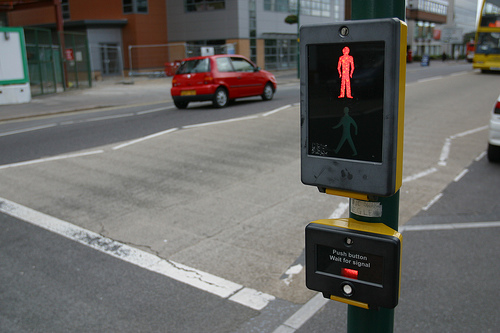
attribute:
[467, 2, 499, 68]
bus — yellow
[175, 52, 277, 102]
car — red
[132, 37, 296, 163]
car — red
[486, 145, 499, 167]
tire — white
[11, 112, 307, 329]
road — asphalt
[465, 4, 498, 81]
bus — double decker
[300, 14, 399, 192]
crosswalk signals — digital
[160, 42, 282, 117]
car — compact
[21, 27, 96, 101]
fence — green, metal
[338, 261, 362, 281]
light — red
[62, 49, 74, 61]
sign — red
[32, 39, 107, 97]
gate — green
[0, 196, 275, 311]
line — white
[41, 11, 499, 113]
building — brick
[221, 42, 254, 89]
windows — dark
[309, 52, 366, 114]
man — red, lit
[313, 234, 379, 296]
button — red, yellow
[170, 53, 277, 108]
car — red,  white 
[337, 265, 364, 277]
button — red, rectangular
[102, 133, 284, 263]
street — wide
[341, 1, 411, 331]
pole — green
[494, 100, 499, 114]
taillight —  red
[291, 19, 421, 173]
signal — grey, yellow, pedestrian box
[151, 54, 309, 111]
car — red, license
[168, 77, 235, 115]
plate — yellow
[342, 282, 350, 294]
button — white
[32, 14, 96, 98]
green gate — tall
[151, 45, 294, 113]
car — red, small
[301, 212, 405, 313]
box — black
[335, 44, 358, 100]
image — red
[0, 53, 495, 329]
street — wide